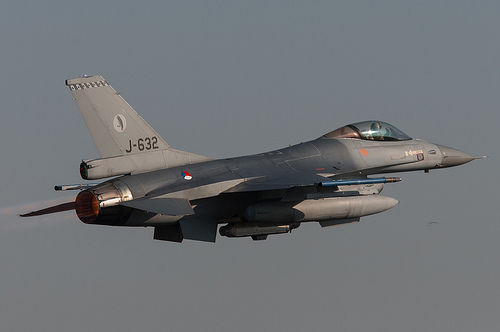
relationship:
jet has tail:
[18, 74, 490, 245] [63, 72, 213, 173]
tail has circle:
[63, 72, 213, 173] [112, 113, 131, 133]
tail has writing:
[63, 72, 213, 173] [126, 135, 165, 155]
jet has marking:
[18, 74, 490, 245] [180, 169, 195, 181]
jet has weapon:
[18, 74, 490, 245] [314, 175, 405, 187]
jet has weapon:
[18, 74, 490, 245] [224, 219, 300, 242]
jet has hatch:
[18, 74, 490, 245] [350, 119, 416, 143]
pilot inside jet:
[371, 122, 386, 142] [18, 74, 490, 245]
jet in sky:
[18, 74, 490, 245] [2, 2, 499, 328]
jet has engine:
[18, 74, 490, 245] [74, 178, 134, 229]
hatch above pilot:
[350, 119, 416, 143] [371, 122, 386, 142]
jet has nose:
[18, 74, 490, 245] [435, 144, 489, 167]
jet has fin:
[18, 74, 490, 245] [181, 214, 221, 243]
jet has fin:
[18, 74, 490, 245] [151, 224, 189, 247]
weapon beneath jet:
[224, 219, 300, 242] [18, 74, 490, 245]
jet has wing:
[18, 74, 490, 245] [238, 167, 404, 198]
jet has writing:
[18, 74, 490, 245] [126, 135, 165, 155]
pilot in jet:
[371, 122, 386, 142] [18, 74, 490, 245]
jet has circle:
[18, 74, 490, 245] [112, 113, 131, 133]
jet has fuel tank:
[18, 74, 490, 245] [245, 191, 405, 221]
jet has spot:
[18, 74, 490, 245] [359, 145, 373, 157]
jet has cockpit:
[18, 74, 490, 245] [365, 135, 400, 147]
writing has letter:
[126, 135, 165, 155] [126, 140, 134, 153]